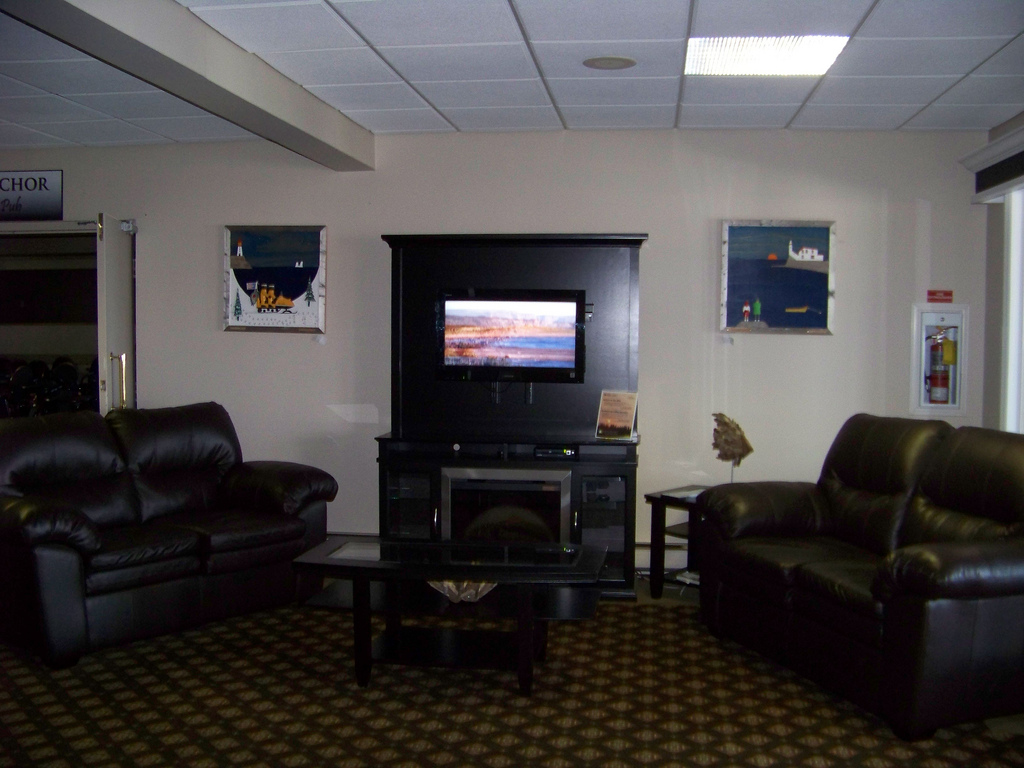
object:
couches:
[0, 401, 1024, 742]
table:
[293, 536, 609, 697]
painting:
[223, 219, 837, 336]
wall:
[0, 130, 989, 574]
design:
[547, 736, 579, 750]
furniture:
[374, 233, 648, 603]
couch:
[696, 414, 1024, 742]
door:
[0, 213, 136, 417]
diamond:
[114, 686, 246, 735]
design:
[331, 725, 363, 738]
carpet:
[0, 568, 1024, 768]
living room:
[0, 0, 1024, 768]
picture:
[720, 218, 838, 335]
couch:
[2, 401, 341, 672]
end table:
[644, 485, 715, 601]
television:
[436, 289, 586, 384]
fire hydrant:
[925, 326, 958, 404]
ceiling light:
[684, 34, 851, 77]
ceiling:
[0, 0, 1024, 148]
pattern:
[265, 711, 294, 723]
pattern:
[684, 679, 710, 690]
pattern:
[502, 714, 531, 727]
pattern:
[530, 706, 559, 719]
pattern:
[486, 689, 512, 701]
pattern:
[378, 699, 407, 710]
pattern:
[659, 644, 681, 654]